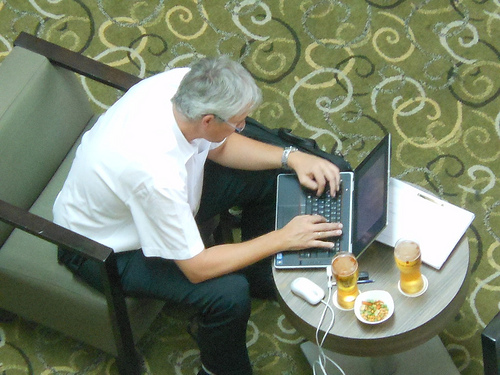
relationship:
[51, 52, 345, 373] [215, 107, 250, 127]
man on eyeglasses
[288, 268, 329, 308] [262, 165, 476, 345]
mouse on table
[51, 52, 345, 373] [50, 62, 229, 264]
man wearing shirt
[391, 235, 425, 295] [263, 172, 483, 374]
glass on table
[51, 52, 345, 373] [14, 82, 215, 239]
man wearing shirt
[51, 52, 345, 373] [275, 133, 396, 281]
man typing on laptop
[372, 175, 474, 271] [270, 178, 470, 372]
folder sitting on table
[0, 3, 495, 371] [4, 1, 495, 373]
carpet has design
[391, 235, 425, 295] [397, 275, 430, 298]
glass sitting on coaster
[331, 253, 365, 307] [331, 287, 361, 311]
glass sitting on coaster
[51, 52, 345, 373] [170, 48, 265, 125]
man has hair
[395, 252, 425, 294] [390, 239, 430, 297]
drink in glass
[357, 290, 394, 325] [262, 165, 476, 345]
bowl sitting on table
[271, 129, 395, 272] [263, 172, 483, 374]
laptop sitting on table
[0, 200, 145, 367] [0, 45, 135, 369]
colored arms on grey chair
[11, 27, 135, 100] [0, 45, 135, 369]
colored arms on grey chair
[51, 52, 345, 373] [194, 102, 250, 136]
man wearing glasses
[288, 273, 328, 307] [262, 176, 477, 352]
mouse on table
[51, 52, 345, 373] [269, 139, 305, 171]
man wearing watch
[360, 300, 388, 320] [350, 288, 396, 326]
food in bowl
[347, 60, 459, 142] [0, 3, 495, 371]
designs in carpet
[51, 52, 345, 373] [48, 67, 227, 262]
man wearing white shirt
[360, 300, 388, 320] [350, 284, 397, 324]
food in bowl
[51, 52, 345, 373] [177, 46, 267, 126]
man has hair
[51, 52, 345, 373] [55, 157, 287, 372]
man wearing jeans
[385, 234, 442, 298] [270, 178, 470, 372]
beer on table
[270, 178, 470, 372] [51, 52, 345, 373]
table close to man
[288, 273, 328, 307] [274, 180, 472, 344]
mouse on table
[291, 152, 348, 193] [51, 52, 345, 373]
hand of man